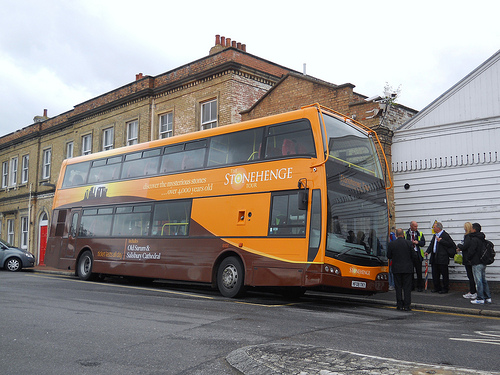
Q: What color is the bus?
A: Yellow and Brown.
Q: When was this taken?
A: Daytime.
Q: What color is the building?
A: Brick.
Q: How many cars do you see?
A: One.